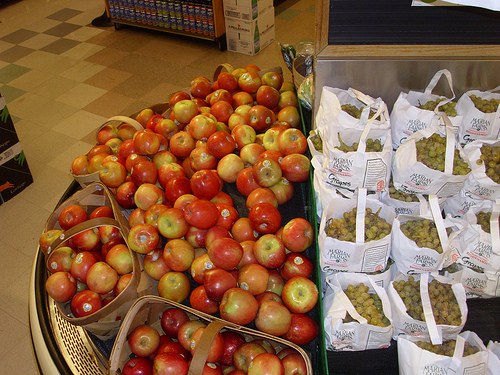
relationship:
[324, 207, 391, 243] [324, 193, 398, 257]
grapes in bag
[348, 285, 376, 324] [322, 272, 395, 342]
grapes in bag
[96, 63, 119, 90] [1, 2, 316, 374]
tile on floor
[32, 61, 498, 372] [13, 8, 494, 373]
display in store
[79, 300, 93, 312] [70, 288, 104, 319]
produce sticker on apple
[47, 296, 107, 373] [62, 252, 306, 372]
grate around display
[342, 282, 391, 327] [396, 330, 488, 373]
grapes in bag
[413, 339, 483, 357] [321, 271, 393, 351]
grapes in bag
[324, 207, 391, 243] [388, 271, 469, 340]
grapes in bag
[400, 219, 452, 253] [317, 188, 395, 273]
grapes in bag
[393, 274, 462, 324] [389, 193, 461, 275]
grapes in bag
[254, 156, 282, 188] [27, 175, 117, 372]
fruit on top of table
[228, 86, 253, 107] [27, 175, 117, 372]
fruit on top of table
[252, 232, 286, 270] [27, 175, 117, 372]
fruit on top of table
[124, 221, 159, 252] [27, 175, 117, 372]
fruit on top of table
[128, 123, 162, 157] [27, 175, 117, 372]
fruit on top of table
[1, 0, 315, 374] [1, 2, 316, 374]
tile on floor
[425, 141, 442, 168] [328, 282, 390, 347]
grapes in bag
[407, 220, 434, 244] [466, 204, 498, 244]
grapes in bag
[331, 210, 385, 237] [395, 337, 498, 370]
grapes in bag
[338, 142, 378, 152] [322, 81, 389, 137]
grapes in bag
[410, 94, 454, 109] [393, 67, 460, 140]
grapes in bag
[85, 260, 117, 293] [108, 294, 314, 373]
apple in basket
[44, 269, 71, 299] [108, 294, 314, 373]
apple in basket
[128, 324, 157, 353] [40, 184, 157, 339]
apple in basket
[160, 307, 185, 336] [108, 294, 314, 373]
apple in basket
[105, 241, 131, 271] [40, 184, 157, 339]
apple in basket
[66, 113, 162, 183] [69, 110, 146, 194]
apples in basket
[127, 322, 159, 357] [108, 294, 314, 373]
apple in basket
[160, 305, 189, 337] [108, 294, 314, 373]
apple in basket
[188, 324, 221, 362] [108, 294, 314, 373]
apple in basket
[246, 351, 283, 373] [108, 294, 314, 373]
apple in basket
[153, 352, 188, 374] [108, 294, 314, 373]
apple in basket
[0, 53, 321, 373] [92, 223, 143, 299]
apples in basket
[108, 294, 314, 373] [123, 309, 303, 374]
basket holding apples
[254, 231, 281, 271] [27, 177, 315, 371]
apple on table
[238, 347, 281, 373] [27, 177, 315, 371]
apple on table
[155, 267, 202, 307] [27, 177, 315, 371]
apple on table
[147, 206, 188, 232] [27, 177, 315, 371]
apple on table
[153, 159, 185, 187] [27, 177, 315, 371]
apple on table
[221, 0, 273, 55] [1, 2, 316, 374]
boxes on floor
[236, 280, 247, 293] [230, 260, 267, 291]
sticker on apple